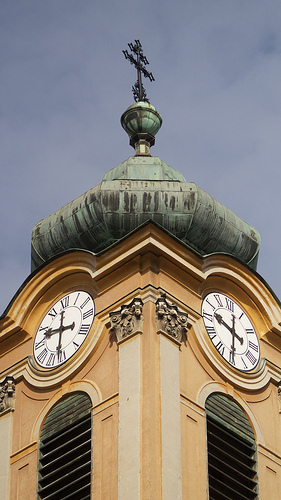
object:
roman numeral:
[72, 293, 82, 305]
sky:
[1, 4, 281, 274]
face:
[27, 290, 95, 369]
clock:
[201, 289, 265, 375]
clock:
[28, 288, 98, 371]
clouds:
[0, 0, 280, 316]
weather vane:
[122, 34, 156, 101]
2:
[79, 296, 90, 311]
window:
[29, 389, 94, 500]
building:
[0, 32, 281, 497]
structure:
[29, 150, 264, 272]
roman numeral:
[59, 294, 71, 312]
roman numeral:
[72, 290, 80, 305]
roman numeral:
[80, 294, 91, 310]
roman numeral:
[81, 306, 93, 320]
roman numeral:
[76, 321, 91, 337]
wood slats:
[215, 394, 243, 412]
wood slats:
[49, 393, 81, 409]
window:
[204, 389, 260, 500]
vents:
[57, 480, 99, 498]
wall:
[95, 353, 184, 494]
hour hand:
[43, 321, 75, 338]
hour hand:
[213, 311, 244, 347]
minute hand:
[229, 314, 236, 364]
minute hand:
[56, 310, 64, 359]